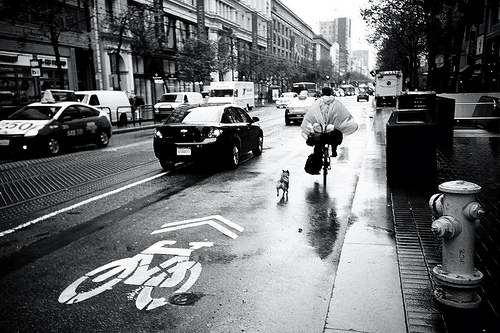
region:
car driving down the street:
[148, 97, 259, 172]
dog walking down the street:
[270, 170, 297, 202]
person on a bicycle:
[306, 72, 357, 189]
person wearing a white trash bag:
[301, 83, 356, 182]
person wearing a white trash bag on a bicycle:
[298, 82, 354, 179]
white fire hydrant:
[423, 185, 484, 318]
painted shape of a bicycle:
[58, 230, 225, 325]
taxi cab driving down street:
[9, 95, 138, 154]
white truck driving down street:
[369, 70, 404, 109]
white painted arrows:
[146, 202, 258, 238]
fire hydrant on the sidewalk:
[428, 178, 486, 308]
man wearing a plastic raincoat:
[301, 85, 358, 197]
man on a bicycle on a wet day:
[301, 86, 358, 190]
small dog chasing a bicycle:
[276, 168, 291, 201]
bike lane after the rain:
[58, 210, 327, 321]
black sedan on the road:
[151, 100, 266, 168]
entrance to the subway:
[438, 92, 498, 136]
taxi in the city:
[2, 88, 114, 155]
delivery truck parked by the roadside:
[374, 68, 397, 108]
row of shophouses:
[0, 0, 332, 82]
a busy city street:
[5, 2, 431, 312]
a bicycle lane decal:
[53, 202, 257, 311]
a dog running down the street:
[262, 155, 298, 232]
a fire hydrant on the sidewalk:
[423, 168, 492, 310]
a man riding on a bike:
[298, 77, 360, 190]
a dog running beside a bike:
[271, 80, 359, 210]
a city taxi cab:
[0, 85, 115, 170]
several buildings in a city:
[0, 0, 335, 77]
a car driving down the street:
[145, 100, 274, 175]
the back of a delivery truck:
[371, 66, 403, 103]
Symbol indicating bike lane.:
[67, 205, 247, 316]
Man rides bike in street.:
[305, 78, 356, 190]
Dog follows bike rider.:
[270, 88, 359, 211]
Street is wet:
[208, 113, 380, 324]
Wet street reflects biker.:
[269, 76, 363, 264]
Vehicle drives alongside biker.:
[149, 82, 363, 225]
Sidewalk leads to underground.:
[435, 91, 499, 167]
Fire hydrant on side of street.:
[420, 181, 497, 312]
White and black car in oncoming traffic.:
[0, 88, 117, 153]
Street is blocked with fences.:
[90, 104, 162, 127]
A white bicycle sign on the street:
[61, 230, 210, 312]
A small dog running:
[270, 167, 295, 202]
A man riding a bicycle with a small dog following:
[269, 87, 358, 206]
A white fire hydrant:
[426, 175, 484, 307]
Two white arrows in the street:
[150, 211, 244, 241]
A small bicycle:
[312, 137, 338, 188]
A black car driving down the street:
[150, 104, 267, 172]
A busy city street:
[14, 81, 372, 177]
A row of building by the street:
[0, 1, 329, 94]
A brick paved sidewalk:
[387, 117, 499, 329]